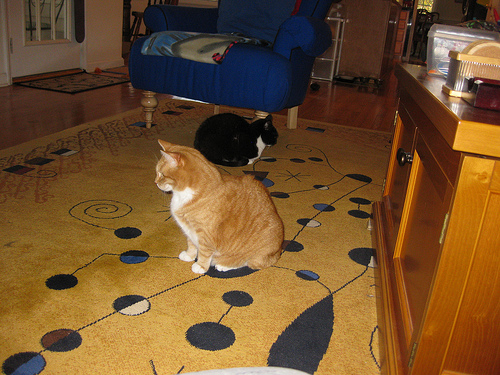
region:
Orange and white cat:
[147, 133, 289, 274]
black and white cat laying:
[192, 109, 287, 166]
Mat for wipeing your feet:
[14, 64, 134, 96]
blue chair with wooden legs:
[123, 4, 340, 144]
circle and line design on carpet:
[41, 249, 118, 295]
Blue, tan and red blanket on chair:
[136, 16, 271, 66]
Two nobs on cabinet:
[388, 142, 415, 171]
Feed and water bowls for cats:
[328, 67, 387, 95]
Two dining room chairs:
[405, 2, 437, 62]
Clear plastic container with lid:
[422, 17, 499, 59]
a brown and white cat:
[147, 142, 287, 273]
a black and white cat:
[185, 110, 279, 170]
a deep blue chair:
[129, 0, 334, 128]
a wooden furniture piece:
[366, 54, 497, 371]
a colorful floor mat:
[9, 67, 124, 95]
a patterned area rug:
[15, 76, 403, 373]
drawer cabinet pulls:
[393, 144, 413, 166]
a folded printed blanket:
[139, 29, 258, 65]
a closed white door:
[5, 3, 86, 82]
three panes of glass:
[20, 1, 68, 46]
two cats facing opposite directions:
[156, 103, 296, 285]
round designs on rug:
[44, 241, 156, 353]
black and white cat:
[202, 112, 282, 168]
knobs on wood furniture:
[378, 140, 417, 169]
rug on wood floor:
[47, 104, 117, 144]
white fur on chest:
[168, 185, 195, 238]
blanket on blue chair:
[129, 26, 260, 76]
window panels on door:
[12, 3, 82, 78]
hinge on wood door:
[432, 207, 454, 243]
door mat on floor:
[21, 66, 133, 106]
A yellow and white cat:
[150, 134, 295, 281]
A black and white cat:
[189, 101, 285, 172]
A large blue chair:
[121, 1, 342, 134]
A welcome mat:
[13, 68, 140, 101]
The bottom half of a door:
[0, 1, 108, 94]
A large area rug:
[2, 84, 419, 373]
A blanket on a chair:
[141, 12, 271, 82]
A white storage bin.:
[307, 6, 345, 91]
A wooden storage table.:
[363, 53, 499, 373]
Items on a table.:
[411, 15, 499, 138]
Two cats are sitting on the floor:
[145, 100, 305, 288]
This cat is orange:
[150, 137, 288, 282]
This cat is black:
[191, 106, 288, 162]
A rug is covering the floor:
[13, 125, 125, 244]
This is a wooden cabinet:
[360, 57, 498, 374]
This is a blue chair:
[129, 2, 340, 122]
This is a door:
[3, 0, 93, 75]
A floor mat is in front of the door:
[9, 52, 125, 105]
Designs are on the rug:
[26, 244, 174, 368]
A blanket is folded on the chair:
[145, 21, 267, 74]